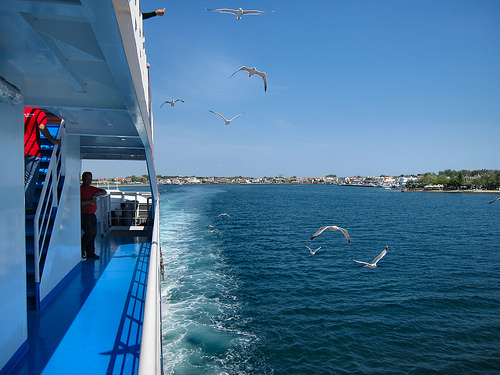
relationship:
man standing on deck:
[75, 169, 106, 263] [7, 192, 163, 371]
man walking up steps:
[21, 103, 58, 216] [23, 120, 86, 308]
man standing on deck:
[75, 169, 112, 266] [6, 226, 153, 369]